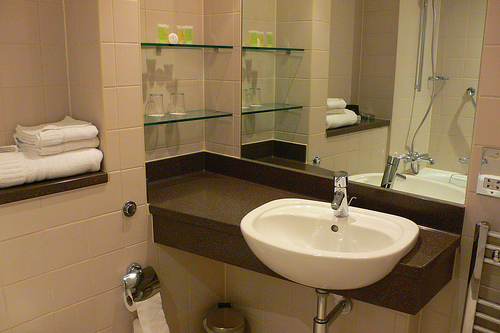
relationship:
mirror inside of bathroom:
[242, 6, 464, 159] [1, 5, 500, 333]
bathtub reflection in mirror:
[421, 161, 473, 187] [242, 6, 464, 159]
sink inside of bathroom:
[238, 194, 423, 293] [1, 5, 500, 333]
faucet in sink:
[331, 169, 355, 220] [238, 194, 423, 293]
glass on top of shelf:
[170, 93, 188, 116] [145, 107, 234, 130]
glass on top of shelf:
[148, 93, 166, 118] [145, 107, 234, 130]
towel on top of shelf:
[3, 152, 105, 180] [1, 171, 112, 204]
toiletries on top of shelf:
[157, 24, 196, 45] [145, 36, 234, 57]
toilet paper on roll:
[127, 293, 170, 332] [129, 266, 162, 299]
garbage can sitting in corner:
[208, 308, 243, 333] [213, 264, 234, 302]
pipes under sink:
[315, 291, 344, 332] [238, 194, 423, 293]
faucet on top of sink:
[331, 169, 355, 220] [238, 194, 423, 293]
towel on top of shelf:
[11, 111, 102, 157] [1, 171, 112, 204]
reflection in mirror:
[381, 156, 406, 187] [242, 6, 464, 159]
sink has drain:
[238, 194, 423, 293] [329, 223, 340, 234]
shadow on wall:
[149, 60, 179, 88] [141, 51, 239, 97]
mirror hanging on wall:
[242, 6, 464, 159] [141, 51, 239, 97]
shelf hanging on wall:
[145, 107, 234, 130] [141, 51, 239, 97]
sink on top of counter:
[238, 194, 423, 293] [158, 166, 240, 258]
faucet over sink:
[331, 169, 355, 220] [238, 194, 423, 293]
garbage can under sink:
[208, 308, 243, 333] [238, 194, 423, 293]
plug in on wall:
[478, 174, 499, 195] [141, 51, 239, 97]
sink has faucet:
[238, 194, 423, 293] [331, 169, 355, 220]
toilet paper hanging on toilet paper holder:
[127, 293, 170, 332] [122, 258, 163, 304]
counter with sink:
[158, 166, 240, 258] [238, 194, 423, 293]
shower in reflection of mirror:
[419, 2, 479, 187] [242, 6, 464, 159]